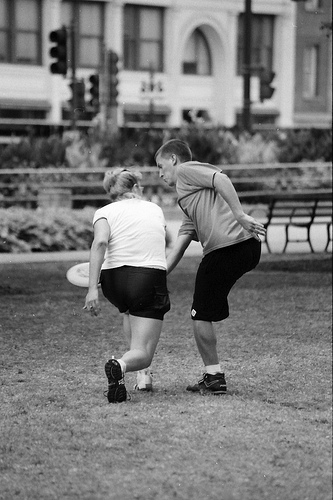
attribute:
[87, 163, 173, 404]
woman — blonde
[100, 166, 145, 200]
hair — blonde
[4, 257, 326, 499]
field — covered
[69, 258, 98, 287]
frisbee — flying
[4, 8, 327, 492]
picture — white, black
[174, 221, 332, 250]
sidewalk — found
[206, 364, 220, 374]
socks — white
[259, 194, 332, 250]
bench — metal, park